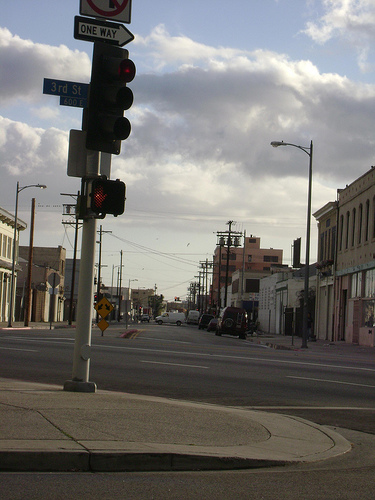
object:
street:
[0, 320, 375, 436]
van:
[215, 307, 247, 341]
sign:
[93, 296, 114, 320]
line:
[140, 358, 208, 368]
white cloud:
[296, 0, 374, 76]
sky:
[0, 0, 375, 302]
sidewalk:
[0, 378, 352, 470]